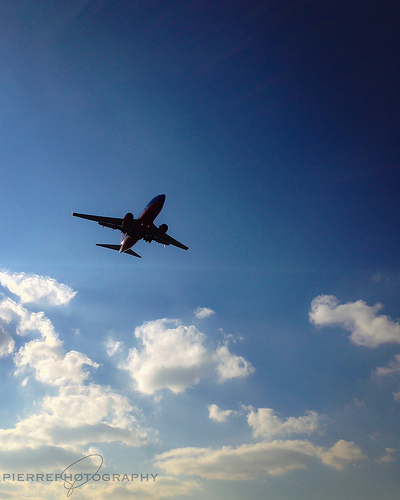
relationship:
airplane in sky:
[73, 194, 190, 257] [3, 3, 397, 492]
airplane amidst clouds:
[73, 194, 190, 257] [0, 269, 399, 499]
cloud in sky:
[308, 294, 397, 350] [3, 3, 397, 492]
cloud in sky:
[107, 319, 252, 394] [3, 3, 397, 492]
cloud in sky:
[1, 270, 143, 478] [3, 3, 397, 492]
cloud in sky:
[5, 437, 365, 499] [3, 3, 397, 492]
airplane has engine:
[73, 194, 190, 257] [121, 213, 133, 230]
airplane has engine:
[73, 194, 190, 257] [154, 224, 167, 242]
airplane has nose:
[73, 194, 190, 257] [139, 193, 165, 225]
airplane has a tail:
[73, 194, 190, 257] [96, 236, 141, 259]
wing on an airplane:
[146, 225, 188, 252] [73, 194, 190, 257]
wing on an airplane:
[73, 211, 137, 234] [73, 194, 190, 257]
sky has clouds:
[3, 3, 397, 492] [0, 269, 399, 499]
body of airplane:
[121, 193, 166, 252] [73, 194, 190, 257]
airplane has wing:
[73, 194, 190, 257] [146, 225, 188, 252]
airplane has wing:
[73, 194, 190, 257] [73, 211, 137, 234]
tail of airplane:
[96, 236, 141, 259] [73, 194, 190, 257]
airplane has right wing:
[73, 194, 190, 257] [146, 225, 188, 252]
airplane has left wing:
[73, 194, 190, 257] [73, 211, 137, 234]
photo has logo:
[2, 0, 399, 499] [3, 458, 159, 495]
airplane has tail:
[73, 194, 190, 257] [96, 236, 141, 259]